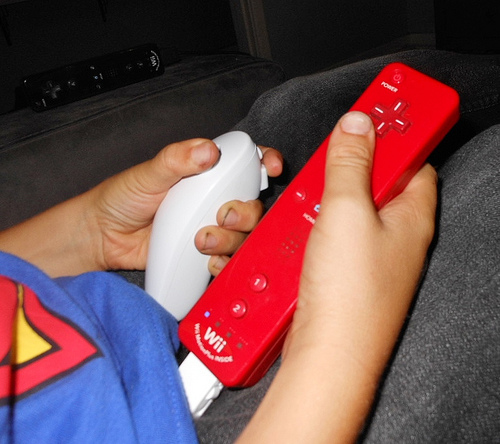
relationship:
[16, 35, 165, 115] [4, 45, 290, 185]
wii remote laying on top of arm of chair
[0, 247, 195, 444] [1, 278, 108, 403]
hem with superman logo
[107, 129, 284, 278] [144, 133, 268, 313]
hand holding wii remote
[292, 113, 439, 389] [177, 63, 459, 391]
hand holding wii remote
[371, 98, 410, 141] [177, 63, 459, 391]
directional button on wii remote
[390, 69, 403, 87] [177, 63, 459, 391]
power button on wii remote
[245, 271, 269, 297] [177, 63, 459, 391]
1 botton on wii remote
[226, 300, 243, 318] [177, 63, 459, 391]
2 button on wii remote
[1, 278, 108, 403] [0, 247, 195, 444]
superman logo on hem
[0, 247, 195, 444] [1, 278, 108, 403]
hem has superman logo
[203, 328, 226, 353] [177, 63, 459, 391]
wii logo on wii remote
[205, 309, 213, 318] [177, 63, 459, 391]
light lit up on wii remote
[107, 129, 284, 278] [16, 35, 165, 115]
hand wrapped around wii remote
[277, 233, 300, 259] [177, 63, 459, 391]
speaker on wii remote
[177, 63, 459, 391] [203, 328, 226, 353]
wii remote has wii logo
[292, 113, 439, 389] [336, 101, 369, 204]
hand has thumb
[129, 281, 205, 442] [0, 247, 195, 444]
hem of hem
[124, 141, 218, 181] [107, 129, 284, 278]
thumb on hand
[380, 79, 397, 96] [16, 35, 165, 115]
power printed on wii remote